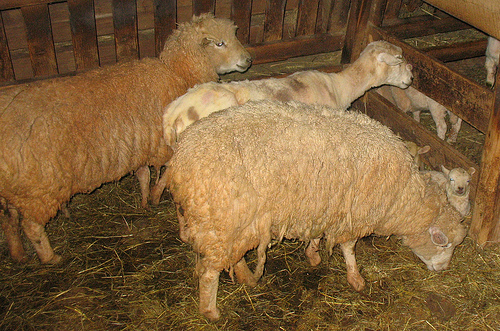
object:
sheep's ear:
[429, 228, 450, 247]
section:
[356, 0, 500, 253]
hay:
[8, 198, 493, 328]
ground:
[6, 193, 498, 329]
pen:
[5, 11, 36, 81]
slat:
[261, 1, 286, 45]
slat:
[329, 2, 346, 35]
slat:
[230, 2, 249, 47]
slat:
[366, 25, 489, 132]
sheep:
[423, 165, 476, 218]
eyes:
[399, 63, 403, 66]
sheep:
[162, 103, 472, 317]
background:
[1, 1, 498, 330]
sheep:
[1, 13, 249, 265]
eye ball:
[218, 43, 223, 46]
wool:
[210, 131, 385, 191]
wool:
[30, 89, 147, 139]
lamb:
[157, 39, 416, 172]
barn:
[2, 0, 500, 328]